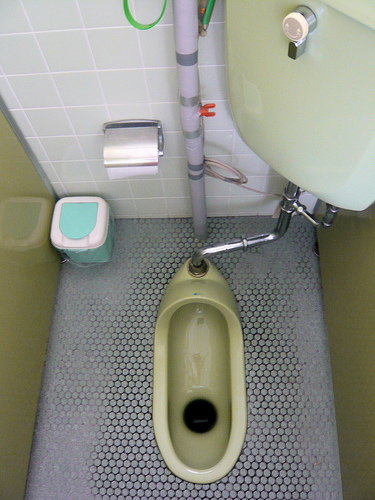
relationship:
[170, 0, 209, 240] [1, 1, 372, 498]
pipe inside bathroom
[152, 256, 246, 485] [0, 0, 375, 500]
bowl inside bathroom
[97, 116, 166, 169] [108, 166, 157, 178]
holder contains toilet paper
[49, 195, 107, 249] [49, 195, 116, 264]
lid on top of receptacle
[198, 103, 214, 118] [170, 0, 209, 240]
knob attached to pipe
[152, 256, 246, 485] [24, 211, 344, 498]
bowl in ground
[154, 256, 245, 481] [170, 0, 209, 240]
bowl has pipe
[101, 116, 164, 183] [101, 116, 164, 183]
holder hanging out of holder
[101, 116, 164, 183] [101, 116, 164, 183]
holder in holder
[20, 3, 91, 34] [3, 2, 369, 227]
tile in wall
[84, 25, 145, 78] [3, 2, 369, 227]
tile in wall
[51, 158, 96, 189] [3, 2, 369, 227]
tile in wall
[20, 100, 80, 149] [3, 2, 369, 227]
tile in wall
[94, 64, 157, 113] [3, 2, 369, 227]
tile in wall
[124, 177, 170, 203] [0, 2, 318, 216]
tile in wall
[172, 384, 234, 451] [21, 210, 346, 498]
hole in floor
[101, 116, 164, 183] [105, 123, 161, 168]
holder in holder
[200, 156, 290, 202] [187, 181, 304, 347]
cord connected to pipe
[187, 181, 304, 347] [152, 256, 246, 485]
pipe connected to bowl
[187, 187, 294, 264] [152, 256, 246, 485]
pipe on bowl